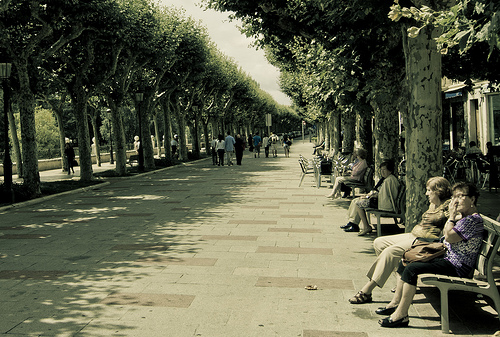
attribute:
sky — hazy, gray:
[158, 16, 324, 126]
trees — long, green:
[23, 3, 294, 169]